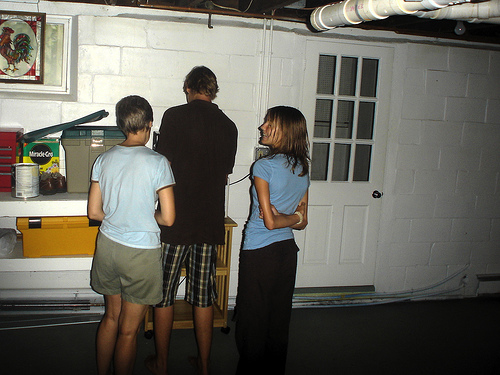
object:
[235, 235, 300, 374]
pants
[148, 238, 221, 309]
shorts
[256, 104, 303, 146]
head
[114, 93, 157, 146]
heads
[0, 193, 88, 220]
table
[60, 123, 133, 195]
container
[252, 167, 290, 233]
arms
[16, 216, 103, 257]
container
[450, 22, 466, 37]
light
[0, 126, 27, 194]
toolbox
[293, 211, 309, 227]
bracelet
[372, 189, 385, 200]
knob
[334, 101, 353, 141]
glass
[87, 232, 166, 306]
shorts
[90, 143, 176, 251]
shirt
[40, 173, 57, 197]
shoes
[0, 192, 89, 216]
counter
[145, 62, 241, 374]
man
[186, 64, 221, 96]
hair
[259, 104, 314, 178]
hair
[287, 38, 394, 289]
door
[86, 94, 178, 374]
person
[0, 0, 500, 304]
wall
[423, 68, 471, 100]
brick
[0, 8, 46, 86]
painting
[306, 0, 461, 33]
pipe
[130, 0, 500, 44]
ceiling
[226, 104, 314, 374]
girl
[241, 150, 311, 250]
t-shirt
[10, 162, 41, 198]
can